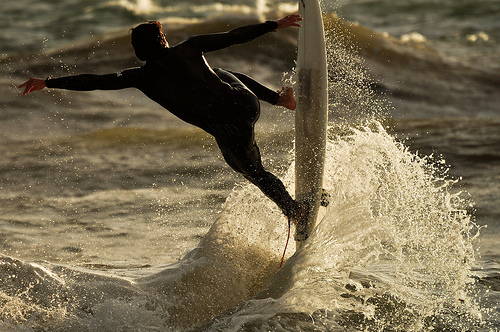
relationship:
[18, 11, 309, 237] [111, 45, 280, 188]
man has wetsuit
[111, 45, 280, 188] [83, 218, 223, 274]
wetsuit in water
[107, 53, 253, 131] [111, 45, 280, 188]
man in wetsuit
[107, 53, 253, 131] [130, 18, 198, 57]
man has head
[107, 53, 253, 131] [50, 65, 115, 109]
man has arm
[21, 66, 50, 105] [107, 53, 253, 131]
hand of man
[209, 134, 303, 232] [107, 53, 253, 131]
leg of man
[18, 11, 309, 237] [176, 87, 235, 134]
man wearing black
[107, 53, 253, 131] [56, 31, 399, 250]
man in ocean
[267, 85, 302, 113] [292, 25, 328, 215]
foot on surfboard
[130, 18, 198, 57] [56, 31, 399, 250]
head in ocean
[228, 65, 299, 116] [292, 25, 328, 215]
legs on surfboard